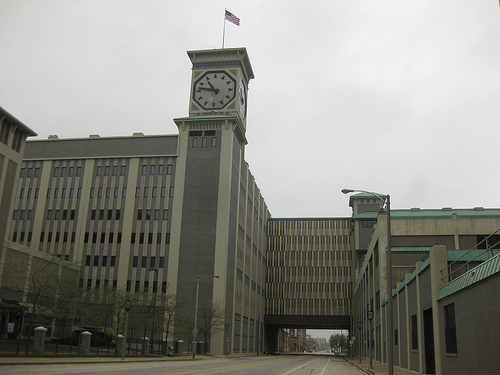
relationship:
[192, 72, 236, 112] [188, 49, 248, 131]
face of clock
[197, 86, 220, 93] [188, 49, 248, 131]
hand of clock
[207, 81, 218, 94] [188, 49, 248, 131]
hand of clock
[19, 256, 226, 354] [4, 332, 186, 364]
trees in courtyard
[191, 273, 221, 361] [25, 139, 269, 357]
street light next to building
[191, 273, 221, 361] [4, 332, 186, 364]
street light next to courtyard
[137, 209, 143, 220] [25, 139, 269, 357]
window on building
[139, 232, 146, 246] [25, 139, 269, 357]
window on building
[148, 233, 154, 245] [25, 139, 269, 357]
window on building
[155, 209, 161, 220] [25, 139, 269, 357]
window on building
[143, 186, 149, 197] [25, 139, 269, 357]
window on building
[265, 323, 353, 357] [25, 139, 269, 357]
an underpass past building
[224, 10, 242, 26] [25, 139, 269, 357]
american flag on top of building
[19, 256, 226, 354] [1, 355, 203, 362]
trees on sidewalk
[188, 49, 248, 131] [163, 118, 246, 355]
clock on tower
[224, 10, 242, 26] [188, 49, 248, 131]
american flag on top of clock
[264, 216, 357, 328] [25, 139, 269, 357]
bridge walkway of building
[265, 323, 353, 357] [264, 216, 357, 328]
an underpass under bridge walkway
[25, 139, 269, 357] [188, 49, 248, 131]
building with clock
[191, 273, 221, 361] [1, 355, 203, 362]
lightpost on sidewalk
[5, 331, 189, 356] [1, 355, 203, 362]
fence along sidewalk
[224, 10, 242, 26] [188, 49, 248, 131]
american flag on clock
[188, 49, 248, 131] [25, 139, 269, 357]
clock on building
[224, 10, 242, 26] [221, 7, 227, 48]
american flag on pole